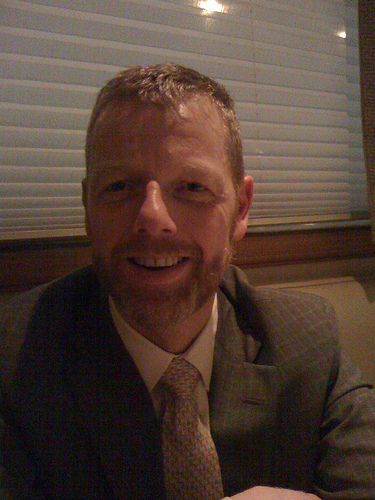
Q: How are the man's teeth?
A: The man's teeth are white.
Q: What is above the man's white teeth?
A: The is a mustache above the man's white teeth.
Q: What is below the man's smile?
A: There is a beard below the man's smile.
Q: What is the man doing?
A: The man is smiling.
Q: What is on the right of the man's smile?
A: The lower lobe of the man's ears is on his right.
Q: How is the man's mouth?
A: The man's mouth is open and smiling.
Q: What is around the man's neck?
A: Tie.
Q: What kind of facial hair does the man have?
A: Beard and moustache.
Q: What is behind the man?
A: Windows.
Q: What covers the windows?
A: Plastic blinds.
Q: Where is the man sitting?
A: In a booth by the window.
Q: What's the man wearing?
A: Suit.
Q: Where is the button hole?
A: On the lapel.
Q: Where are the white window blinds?
A: Behind the man.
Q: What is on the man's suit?
A: Grid pattern.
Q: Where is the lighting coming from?
A: The ceiling.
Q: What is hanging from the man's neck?
A: Tie.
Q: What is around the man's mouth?
A: Goatee.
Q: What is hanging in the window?
A: Blinds.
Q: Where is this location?
A: Restaurant.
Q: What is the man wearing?
A: Suit.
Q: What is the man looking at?
A: Camera.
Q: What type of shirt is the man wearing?
A: Collared.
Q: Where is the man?
A: Sitting in a booth.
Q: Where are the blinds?
A: On the window.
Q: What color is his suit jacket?
A: Gray.